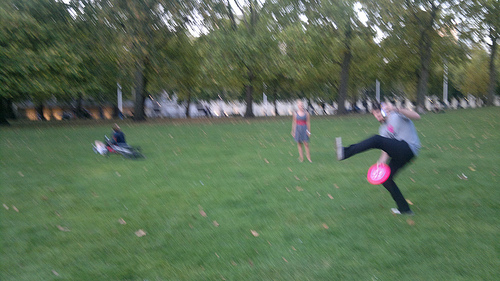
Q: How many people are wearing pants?
A: One.